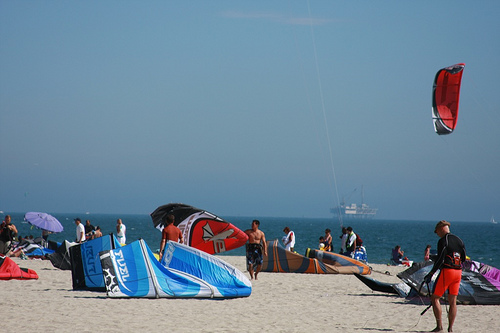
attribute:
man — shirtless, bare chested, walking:
[243, 219, 268, 280]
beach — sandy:
[1, 256, 500, 333]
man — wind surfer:
[424, 220, 466, 332]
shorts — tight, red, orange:
[432, 266, 462, 299]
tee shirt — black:
[430, 233, 465, 275]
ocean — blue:
[3, 212, 500, 269]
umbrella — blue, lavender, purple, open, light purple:
[24, 211, 64, 233]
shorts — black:
[247, 244, 263, 265]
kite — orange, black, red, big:
[431, 62, 465, 134]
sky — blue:
[1, 1, 500, 224]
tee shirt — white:
[76, 223, 85, 240]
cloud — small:
[221, 12, 329, 28]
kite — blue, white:
[99, 240, 253, 298]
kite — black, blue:
[69, 235, 124, 290]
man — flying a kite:
[340, 226, 349, 254]